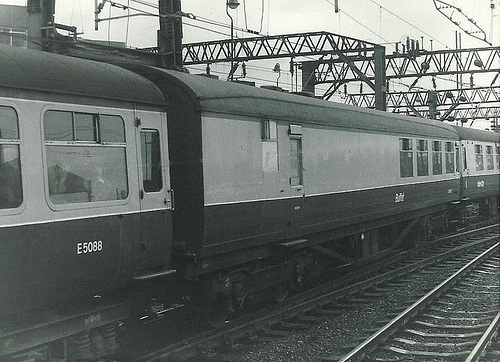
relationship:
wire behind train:
[124, 0, 249, 35] [0, 45, 498, 362]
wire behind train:
[90, 4, 245, 48] [0, 45, 498, 362]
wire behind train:
[364, 0, 449, 53] [0, 45, 498, 362]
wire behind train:
[324, 0, 407, 53] [0, 45, 498, 362]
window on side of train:
[44, 114, 129, 207] [0, 45, 498, 362]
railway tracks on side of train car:
[122, 215, 499, 360] [204, 87, 459, 239]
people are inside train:
[61, 149, 133, 194] [8, 26, 498, 318]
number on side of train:
[72, 239, 104, 254] [0, 45, 498, 362]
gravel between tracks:
[113, 217, 498, 359] [107, 210, 498, 359]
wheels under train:
[0, 189, 494, 356] [0, 45, 498, 362]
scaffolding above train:
[137, 30, 498, 132] [0, 45, 498, 362]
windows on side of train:
[397, 137, 458, 178] [4, 38, 492, 245]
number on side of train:
[393, 188, 423, 202] [0, 45, 498, 362]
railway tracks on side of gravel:
[122, 215, 499, 360] [227, 230, 494, 360]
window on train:
[400, 138, 415, 176] [0, 45, 498, 362]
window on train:
[417, 139, 430, 174] [0, 45, 498, 362]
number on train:
[72, 239, 104, 254] [68, 55, 425, 272]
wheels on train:
[0, 189, 494, 356] [153, 41, 488, 296]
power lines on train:
[91, 0, 499, 131] [0, 45, 498, 362]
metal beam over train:
[393, 105, 498, 123] [0, 45, 498, 362]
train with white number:
[2, 45, 498, 306] [74, 241, 104, 253]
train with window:
[0, 45, 498, 362] [39, 100, 127, 206]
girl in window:
[50, 149, 69, 191] [42, 106, 147, 211]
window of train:
[42, 106, 147, 211] [0, 45, 498, 362]